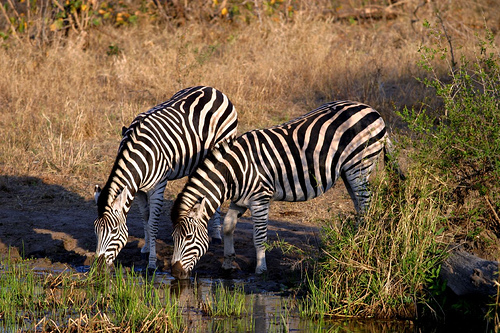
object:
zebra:
[171, 100, 422, 279]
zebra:
[93, 85, 239, 275]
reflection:
[265, 293, 298, 331]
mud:
[0, 263, 197, 332]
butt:
[336, 101, 382, 156]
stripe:
[213, 117, 238, 147]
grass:
[0, 186, 478, 331]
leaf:
[221, 7, 228, 15]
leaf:
[98, 9, 107, 15]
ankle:
[256, 245, 267, 252]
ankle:
[148, 255, 157, 262]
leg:
[250, 201, 269, 277]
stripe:
[254, 221, 267, 223]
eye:
[185, 234, 193, 240]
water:
[0, 260, 500, 331]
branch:
[432, 2, 455, 68]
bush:
[386, 52, 499, 260]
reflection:
[318, 320, 434, 333]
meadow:
[0, 1, 500, 331]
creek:
[0, 265, 500, 333]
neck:
[103, 142, 142, 210]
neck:
[177, 164, 228, 218]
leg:
[146, 192, 164, 276]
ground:
[4, 0, 500, 260]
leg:
[211, 207, 222, 245]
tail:
[384, 131, 421, 194]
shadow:
[1, 174, 101, 268]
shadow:
[95, 177, 340, 275]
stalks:
[22, 239, 25, 260]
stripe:
[198, 161, 226, 202]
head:
[170, 198, 210, 280]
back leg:
[345, 153, 381, 216]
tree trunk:
[436, 242, 498, 296]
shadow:
[311, 66, 448, 121]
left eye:
[111, 228, 118, 234]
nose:
[170, 262, 184, 278]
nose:
[96, 258, 109, 270]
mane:
[170, 135, 237, 226]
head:
[91, 184, 130, 275]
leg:
[221, 207, 243, 272]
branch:
[395, 111, 467, 155]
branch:
[479, 62, 486, 95]